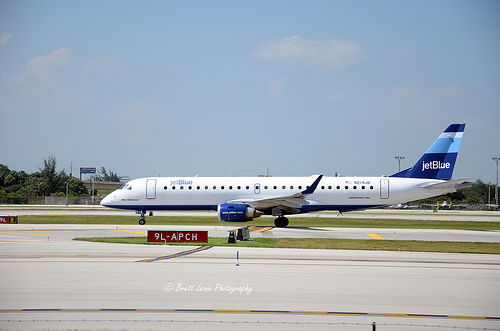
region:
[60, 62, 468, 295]
airplane on the ground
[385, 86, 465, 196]
blue horizontal stripes on tail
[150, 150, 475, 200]
name of airlines on body and tail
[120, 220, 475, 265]
red and white sign on strip of grass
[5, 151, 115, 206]
trees and low building along side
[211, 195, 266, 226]
white writing on blue engine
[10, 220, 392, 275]
yellow lines on grey pavement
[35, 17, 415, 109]
faint white clouds on blue sky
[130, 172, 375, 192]
dark windows on side of plane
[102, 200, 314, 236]
plane wheels touching ground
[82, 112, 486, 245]
blue and white airplane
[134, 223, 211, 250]
sign with white letters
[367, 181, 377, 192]
window on an airplane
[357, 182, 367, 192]
window on an airplane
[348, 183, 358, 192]
window on an airplane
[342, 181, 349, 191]
window on an airplane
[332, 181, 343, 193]
window on an airplane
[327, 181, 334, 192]
window on an airplane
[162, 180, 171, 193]
window on an airplane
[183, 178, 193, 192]
window on an airplane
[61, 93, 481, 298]
plane on the runway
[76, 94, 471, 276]
big plane on the runway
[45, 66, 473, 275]
large plane on the runway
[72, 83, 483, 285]
huge plane on the runway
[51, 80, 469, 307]
full size plane on the runway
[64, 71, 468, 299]
powerful plane on the runway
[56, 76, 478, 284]
heavy plane on the runway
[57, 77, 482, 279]
white plane on the runway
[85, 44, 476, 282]
jetblue plane on the runway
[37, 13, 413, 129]
patch of blue sky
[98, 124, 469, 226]
white and blue airplane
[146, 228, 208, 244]
red sign by the runway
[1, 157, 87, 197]
green deciduous trees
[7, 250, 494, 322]
empty cement runway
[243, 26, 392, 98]
white cloud in blue sky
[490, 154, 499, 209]
tall light pole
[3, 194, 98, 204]
silver chain link fence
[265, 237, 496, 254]
grass in between landing strips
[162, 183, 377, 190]
25 small round airplane windows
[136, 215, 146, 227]
small round black tire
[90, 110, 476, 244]
a white and blue airplane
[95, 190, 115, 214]
the nose of an airplane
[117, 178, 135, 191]
cockpit windows on an airplane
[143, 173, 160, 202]
a door on an airplane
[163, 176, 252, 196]
a line of windows on an airplane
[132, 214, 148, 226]
the nose wheel of an airplane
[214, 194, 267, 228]
the jet engine of an airplane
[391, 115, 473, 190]
a blue tail on an airplane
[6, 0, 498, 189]
a blue cloudy sky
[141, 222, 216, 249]
a red sign along the taxi way